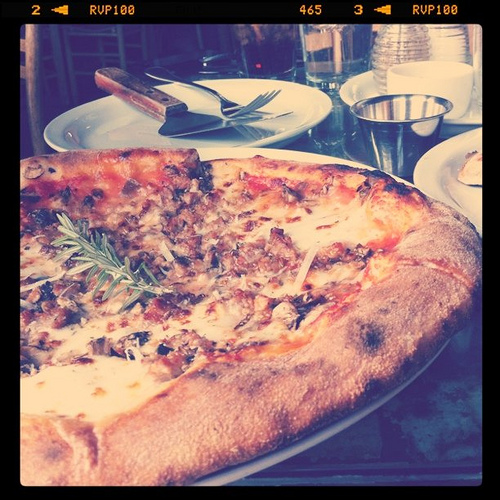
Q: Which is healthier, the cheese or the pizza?
A: The cheese is healthier than the pizza.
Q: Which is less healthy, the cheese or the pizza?
A: The pizza is less healthy than the cheese.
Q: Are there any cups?
A: Yes, there is a cup.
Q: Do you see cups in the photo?
A: Yes, there is a cup.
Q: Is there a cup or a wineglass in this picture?
A: Yes, there is a cup.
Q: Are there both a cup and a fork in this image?
A: Yes, there are both a cup and a fork.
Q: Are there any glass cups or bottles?
A: Yes, there is a glass cup.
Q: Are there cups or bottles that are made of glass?
A: Yes, the cup is made of glass.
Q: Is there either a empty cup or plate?
A: Yes, there is an empty cup.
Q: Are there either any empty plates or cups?
A: Yes, there is an empty cup.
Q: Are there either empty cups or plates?
A: Yes, there is an empty cup.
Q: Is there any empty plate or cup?
A: Yes, there is an empty cup.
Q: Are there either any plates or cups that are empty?
A: Yes, the cup is empty.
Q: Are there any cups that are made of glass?
A: Yes, there is a cup that is made of glass.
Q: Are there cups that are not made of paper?
A: Yes, there is a cup that is made of glass.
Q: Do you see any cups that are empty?
A: Yes, there is an empty cup.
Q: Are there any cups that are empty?
A: Yes, there is a cup that is empty.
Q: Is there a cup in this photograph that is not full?
A: Yes, there is a empty cup.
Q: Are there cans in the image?
A: No, there are no cans.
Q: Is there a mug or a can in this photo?
A: No, there are no cans or mugs.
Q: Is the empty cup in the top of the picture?
A: Yes, the cup is in the top of the image.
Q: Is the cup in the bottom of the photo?
A: No, the cup is in the top of the image.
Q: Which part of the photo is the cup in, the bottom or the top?
A: The cup is in the top of the image.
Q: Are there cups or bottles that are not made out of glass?
A: No, there is a cup but it is made of glass.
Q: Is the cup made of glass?
A: Yes, the cup is made of glass.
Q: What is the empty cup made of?
A: The cup is made of glass.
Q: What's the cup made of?
A: The cup is made of glass.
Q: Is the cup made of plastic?
A: No, the cup is made of glass.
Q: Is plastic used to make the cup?
A: No, the cup is made of glass.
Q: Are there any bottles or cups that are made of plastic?
A: No, there is a cup but it is made of glass.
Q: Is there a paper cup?
A: No, there is a cup but it is made of glass.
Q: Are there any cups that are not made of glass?
A: No, there is a cup but it is made of glass.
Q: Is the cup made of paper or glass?
A: The cup is made of glass.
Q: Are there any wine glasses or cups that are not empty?
A: No, there is a cup but it is empty.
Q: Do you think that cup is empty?
A: Yes, the cup is empty.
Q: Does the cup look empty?
A: Yes, the cup is empty.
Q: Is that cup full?
A: No, the cup is empty.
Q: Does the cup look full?
A: No, the cup is empty.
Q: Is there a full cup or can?
A: No, there is a cup but it is empty.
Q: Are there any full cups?
A: No, there is a cup but it is empty.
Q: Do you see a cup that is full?
A: No, there is a cup but it is empty.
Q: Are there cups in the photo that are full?
A: No, there is a cup but it is empty.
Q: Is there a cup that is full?
A: No, there is a cup but it is empty.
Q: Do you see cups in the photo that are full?
A: No, there is a cup but it is empty.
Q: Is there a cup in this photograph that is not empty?
A: No, there is a cup but it is empty.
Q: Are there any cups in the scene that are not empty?
A: No, there is a cup but it is empty.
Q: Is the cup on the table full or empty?
A: The cup is empty.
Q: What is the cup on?
A: The cup is on the table.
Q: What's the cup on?
A: The cup is on the table.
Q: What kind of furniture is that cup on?
A: The cup is on the table.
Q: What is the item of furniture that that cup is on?
A: The piece of furniture is a table.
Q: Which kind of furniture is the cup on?
A: The cup is on the table.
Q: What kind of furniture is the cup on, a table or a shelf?
A: The cup is on a table.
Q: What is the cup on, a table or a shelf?
A: The cup is on a table.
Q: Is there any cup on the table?
A: Yes, there is a cup on the table.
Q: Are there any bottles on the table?
A: No, there is a cup on the table.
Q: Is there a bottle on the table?
A: No, there is a cup on the table.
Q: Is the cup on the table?
A: Yes, the cup is on the table.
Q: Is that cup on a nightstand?
A: No, the cup is on the table.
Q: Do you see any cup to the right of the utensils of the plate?
A: Yes, there is a cup to the right of the utensils.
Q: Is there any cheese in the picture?
A: Yes, there is cheese.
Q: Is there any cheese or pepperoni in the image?
A: Yes, there is cheese.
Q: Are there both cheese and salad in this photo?
A: No, there is cheese but no salad.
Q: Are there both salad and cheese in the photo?
A: No, there is cheese but no salad.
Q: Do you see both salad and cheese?
A: No, there is cheese but no salad.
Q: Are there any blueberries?
A: No, there are no blueberries.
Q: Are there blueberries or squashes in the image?
A: No, there are no blueberries or squashes.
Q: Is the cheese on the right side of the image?
A: No, the cheese is on the left of the image.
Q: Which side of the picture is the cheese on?
A: The cheese is on the left of the image.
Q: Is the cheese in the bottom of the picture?
A: Yes, the cheese is in the bottom of the image.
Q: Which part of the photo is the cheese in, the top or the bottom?
A: The cheese is in the bottom of the image.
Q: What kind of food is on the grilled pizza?
A: The food is cheese.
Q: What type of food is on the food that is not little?
A: The food is cheese.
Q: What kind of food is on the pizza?
A: The food is cheese.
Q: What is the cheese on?
A: The cheese is on the pizza.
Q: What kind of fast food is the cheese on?
A: The cheese is on the pizza.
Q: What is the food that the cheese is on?
A: The food is a pizza.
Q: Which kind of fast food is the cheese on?
A: The cheese is on the pizza.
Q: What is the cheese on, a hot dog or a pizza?
A: The cheese is on a pizza.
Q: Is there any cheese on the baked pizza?
A: Yes, there is cheese on the pizza.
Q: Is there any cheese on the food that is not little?
A: Yes, there is cheese on the pizza.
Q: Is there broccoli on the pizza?
A: No, there is cheese on the pizza.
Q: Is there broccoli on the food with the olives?
A: No, there is cheese on the pizza.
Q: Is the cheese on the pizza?
A: Yes, the cheese is on the pizza.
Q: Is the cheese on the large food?
A: Yes, the cheese is on the pizza.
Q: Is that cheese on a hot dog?
A: No, the cheese is on the pizza.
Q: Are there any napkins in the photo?
A: No, there are no napkins.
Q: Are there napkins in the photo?
A: No, there are no napkins.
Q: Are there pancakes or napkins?
A: No, there are no napkins or pancakes.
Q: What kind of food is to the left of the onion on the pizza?
A: The food is a sausage.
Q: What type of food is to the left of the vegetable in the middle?
A: The food is a sausage.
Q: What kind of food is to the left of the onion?
A: The food is a sausage.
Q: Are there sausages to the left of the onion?
A: Yes, there is a sausage to the left of the onion.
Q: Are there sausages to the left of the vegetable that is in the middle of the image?
A: Yes, there is a sausage to the left of the onion.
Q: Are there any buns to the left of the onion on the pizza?
A: No, there is a sausage to the left of the onion.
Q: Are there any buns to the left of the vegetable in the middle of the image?
A: No, there is a sausage to the left of the onion.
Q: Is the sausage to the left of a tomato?
A: No, the sausage is to the left of the onion.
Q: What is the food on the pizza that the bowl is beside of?
A: The food is a sausage.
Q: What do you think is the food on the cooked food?
A: The food is a sausage.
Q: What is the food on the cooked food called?
A: The food is a sausage.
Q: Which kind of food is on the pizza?
A: The food is a sausage.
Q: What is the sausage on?
A: The sausage is on the pizza.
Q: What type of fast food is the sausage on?
A: The sausage is on the pizza.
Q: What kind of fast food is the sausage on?
A: The sausage is on the pizza.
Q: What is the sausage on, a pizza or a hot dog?
A: The sausage is on a pizza.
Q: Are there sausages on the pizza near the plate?
A: Yes, there is a sausage on the pizza.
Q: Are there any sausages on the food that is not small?
A: Yes, there is a sausage on the pizza.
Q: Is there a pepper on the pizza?
A: No, there is a sausage on the pizza.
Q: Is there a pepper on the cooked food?
A: No, there is a sausage on the pizza.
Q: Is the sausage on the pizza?
A: Yes, the sausage is on the pizza.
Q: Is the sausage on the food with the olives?
A: Yes, the sausage is on the pizza.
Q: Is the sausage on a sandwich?
A: No, the sausage is on the pizza.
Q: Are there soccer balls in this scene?
A: No, there are no soccer balls.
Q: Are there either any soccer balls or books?
A: No, there are no soccer balls or books.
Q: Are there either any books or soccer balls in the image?
A: No, there are no soccer balls or books.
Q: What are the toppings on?
A: The toppings are on the pizza.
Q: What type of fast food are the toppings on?
A: The toppings are on the pizza.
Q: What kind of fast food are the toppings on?
A: The toppings are on the pizza.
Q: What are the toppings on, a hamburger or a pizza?
A: The toppings are on a pizza.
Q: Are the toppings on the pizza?
A: Yes, the toppings are on the pizza.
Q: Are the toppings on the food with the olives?
A: Yes, the toppings are on the pizza.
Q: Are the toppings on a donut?
A: No, the toppings are on the pizza.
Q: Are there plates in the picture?
A: Yes, there is a plate.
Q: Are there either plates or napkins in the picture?
A: Yes, there is a plate.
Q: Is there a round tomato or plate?
A: Yes, there is a round plate.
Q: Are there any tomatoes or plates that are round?
A: Yes, the plate is round.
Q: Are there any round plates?
A: Yes, there is a round plate.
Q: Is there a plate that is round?
A: Yes, there is a plate that is round.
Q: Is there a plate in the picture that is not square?
A: Yes, there is a round plate.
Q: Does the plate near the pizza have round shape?
A: Yes, the plate is round.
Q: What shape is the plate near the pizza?
A: The plate is round.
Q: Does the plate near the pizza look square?
A: No, the plate is round.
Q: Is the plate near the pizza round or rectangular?
A: The plate is round.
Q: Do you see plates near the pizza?
A: Yes, there is a plate near the pizza.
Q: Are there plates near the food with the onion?
A: Yes, there is a plate near the pizza.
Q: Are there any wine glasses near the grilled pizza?
A: No, there is a plate near the pizza.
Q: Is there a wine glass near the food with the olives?
A: No, there is a plate near the pizza.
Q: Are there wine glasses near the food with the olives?
A: No, there is a plate near the pizza.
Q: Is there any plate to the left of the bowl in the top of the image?
A: Yes, there is a plate to the left of the bowl.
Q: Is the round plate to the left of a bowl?
A: Yes, the plate is to the left of a bowl.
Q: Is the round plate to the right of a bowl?
A: No, the plate is to the left of a bowl.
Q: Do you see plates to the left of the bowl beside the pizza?
A: Yes, there is a plate to the left of the bowl.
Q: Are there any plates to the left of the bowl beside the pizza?
A: Yes, there is a plate to the left of the bowl.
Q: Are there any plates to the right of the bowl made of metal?
A: No, the plate is to the left of the bowl.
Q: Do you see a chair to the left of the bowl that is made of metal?
A: No, there is a plate to the left of the bowl.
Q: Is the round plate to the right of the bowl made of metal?
A: No, the plate is to the left of the bowl.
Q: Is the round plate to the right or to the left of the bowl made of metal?
A: The plate is to the left of the bowl.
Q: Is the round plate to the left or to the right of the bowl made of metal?
A: The plate is to the left of the bowl.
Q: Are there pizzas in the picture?
A: Yes, there is a pizza.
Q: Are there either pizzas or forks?
A: Yes, there is a pizza.